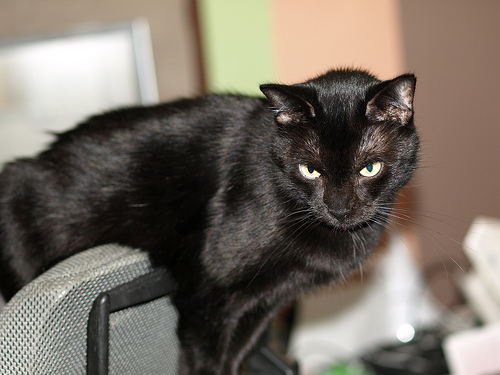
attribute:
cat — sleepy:
[3, 70, 418, 372]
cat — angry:
[35, 34, 447, 332]